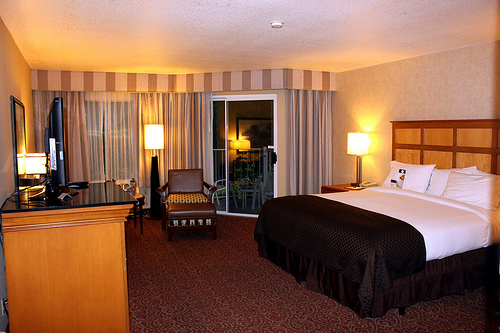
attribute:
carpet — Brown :
[115, 191, 351, 328]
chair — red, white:
[158, 165, 220, 242]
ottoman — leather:
[164, 200, 221, 229]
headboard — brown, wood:
[377, 117, 499, 178]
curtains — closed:
[7, 90, 211, 203]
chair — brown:
[156, 163, 219, 239]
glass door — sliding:
[210, 97, 282, 221]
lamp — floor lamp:
[143, 122, 169, 220]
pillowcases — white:
[381, 159, 498, 211]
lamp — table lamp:
[333, 132, 398, 206]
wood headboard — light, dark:
[390, 118, 499, 174]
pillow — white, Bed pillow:
[448, 170, 496, 216]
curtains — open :
[149, 93, 360, 205]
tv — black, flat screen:
[39, 92, 71, 191]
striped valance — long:
[26, 58, 346, 95]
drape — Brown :
[39, 92, 91, 186]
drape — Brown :
[139, 92, 198, 207]